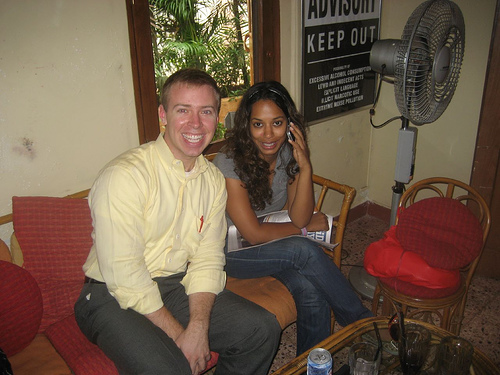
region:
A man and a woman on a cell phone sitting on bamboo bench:
[68, 66, 369, 373]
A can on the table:
[308, 349, 331, 374]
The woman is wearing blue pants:
[226, 240, 376, 352]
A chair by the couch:
[372, 177, 489, 334]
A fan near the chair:
[368, 4, 466, 232]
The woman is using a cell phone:
[286, 120, 294, 141]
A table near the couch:
[274, 319, 496, 373]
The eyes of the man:
[173, 106, 213, 116]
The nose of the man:
[188, 112, 203, 129]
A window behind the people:
[151, 2, 254, 144]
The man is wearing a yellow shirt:
[82, 135, 228, 312]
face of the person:
[138, 63, 319, 181]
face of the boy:
[146, 59, 236, 197]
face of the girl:
[238, 72, 313, 172]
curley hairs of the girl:
[227, 120, 277, 211]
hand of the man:
[141, 285, 231, 372]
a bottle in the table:
[283, 338, 351, 373]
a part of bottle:
[297, 322, 329, 362]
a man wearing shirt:
[81, 133, 215, 284]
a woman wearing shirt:
[201, 108, 339, 247]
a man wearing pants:
[106, 289, 263, 363]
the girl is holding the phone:
[229, 71, 324, 182]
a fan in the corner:
[370, 6, 474, 179]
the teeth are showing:
[244, 137, 281, 157]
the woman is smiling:
[230, 77, 297, 160]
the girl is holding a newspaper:
[211, 175, 365, 322]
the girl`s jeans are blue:
[226, 196, 360, 320]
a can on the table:
[285, 336, 337, 370]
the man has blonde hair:
[142, 53, 224, 125]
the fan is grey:
[350, 2, 465, 163]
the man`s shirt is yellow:
[58, 130, 243, 307]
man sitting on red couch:
[70, 54, 249, 373]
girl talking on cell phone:
[224, 65, 327, 207]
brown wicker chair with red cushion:
[373, 154, 491, 338]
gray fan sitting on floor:
[348, 0, 478, 309]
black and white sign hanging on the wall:
[280, 0, 394, 140]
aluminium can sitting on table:
[298, 335, 331, 374]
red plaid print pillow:
[0, 251, 55, 360]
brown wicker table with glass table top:
[281, 302, 494, 369]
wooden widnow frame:
[118, 2, 170, 149]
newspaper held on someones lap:
[214, 197, 351, 267]